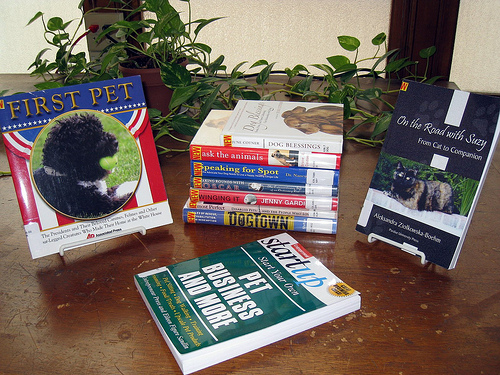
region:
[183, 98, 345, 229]
books stacked on table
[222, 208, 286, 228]
yellow spine of book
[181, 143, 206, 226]
yellow and red stickers on books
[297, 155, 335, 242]
white labels on bottom of books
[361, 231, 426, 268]
white metal book stand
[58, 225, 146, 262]
white metal book stand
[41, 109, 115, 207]
black dog with ball in mouth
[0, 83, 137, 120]
blue top of book with writing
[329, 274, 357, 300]
yellow award on top of book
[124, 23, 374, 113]
green plants on back of table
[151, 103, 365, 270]
Books on the table.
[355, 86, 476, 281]
A book on the rack.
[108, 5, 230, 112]
Plant pot on the table.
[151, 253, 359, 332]
Book on the table.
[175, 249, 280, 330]
Cover of the book is green and white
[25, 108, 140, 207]
A dog in front of the book.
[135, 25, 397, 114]
The plant vine is long.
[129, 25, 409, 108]
Leaves o the plant.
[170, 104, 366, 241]
Books are stacked high on the table.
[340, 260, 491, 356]
The table have marks and scratches.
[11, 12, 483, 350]
books on a table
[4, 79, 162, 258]
a book about pets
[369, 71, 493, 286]
this book is about a cat named Suzy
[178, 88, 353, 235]
a stack of 7 books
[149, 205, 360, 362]
a pet business start up book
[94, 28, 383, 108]
leaves on a table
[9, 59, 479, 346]
books on display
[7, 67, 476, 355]
these books are about dogs and cats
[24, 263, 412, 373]
this table is old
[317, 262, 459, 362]
there are chips on the table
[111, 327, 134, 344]
A spot on the brown surface.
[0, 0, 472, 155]
A green growing plant.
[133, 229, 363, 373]
A book laying on a table.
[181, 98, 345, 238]
A stack of colorful books.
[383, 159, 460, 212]
A cat on a book cover.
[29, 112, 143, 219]
A dog on a book cover.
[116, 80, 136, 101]
The letter T on a book cover.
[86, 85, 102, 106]
The letter P on a book cover.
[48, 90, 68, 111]
The letter S on a book cover.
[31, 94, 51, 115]
The letter R on a book cover.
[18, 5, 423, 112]
a plant on a table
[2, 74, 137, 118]
a book titled First Pet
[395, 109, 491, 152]
a book titled On the Road with Suzy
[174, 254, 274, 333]
words that say Pet Business and More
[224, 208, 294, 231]
a book titled DogTown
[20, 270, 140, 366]
scuff marks in wood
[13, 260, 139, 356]
scuff marks on a table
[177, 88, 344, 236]
a stack of books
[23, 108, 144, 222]
a black dog on a book